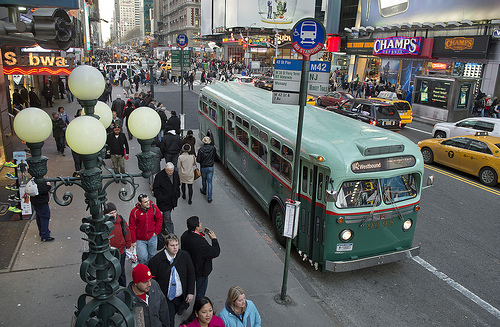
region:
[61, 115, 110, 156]
A big white lamp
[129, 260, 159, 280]
A red stylish cap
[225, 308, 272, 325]
A sky blue jacket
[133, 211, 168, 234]
A beautiful red jacket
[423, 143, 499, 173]
A yellow taxi vehicle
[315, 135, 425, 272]
A big green bus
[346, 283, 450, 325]
A grey tarmacked road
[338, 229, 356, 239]
A small head light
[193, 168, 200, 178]
A small brown bag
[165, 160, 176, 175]
A white haired head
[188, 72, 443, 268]
green bus parked on street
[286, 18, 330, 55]
blue, white, and red bus stop sign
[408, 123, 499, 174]
yellow cab on street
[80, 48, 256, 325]
people walking down sidewalk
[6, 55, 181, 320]
street light with four bulbs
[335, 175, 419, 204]
front window of green bus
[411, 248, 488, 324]
white line on road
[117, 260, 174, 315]
man wearing red hat with white logo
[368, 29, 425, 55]
champs sign across street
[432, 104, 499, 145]
white car driving down street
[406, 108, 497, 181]
the car is yellow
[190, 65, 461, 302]
the bus is green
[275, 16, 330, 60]
the sign is blue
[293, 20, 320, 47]
white bus on sign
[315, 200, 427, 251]
lights on bus are on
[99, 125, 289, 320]
people standing on sidewalk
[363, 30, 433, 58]
white letters on the sign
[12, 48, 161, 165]
street lights are white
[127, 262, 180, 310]
man is wearing a hat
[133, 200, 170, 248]
man's jacket is red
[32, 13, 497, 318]
A busy city street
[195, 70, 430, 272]
A two tone green bus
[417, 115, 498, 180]
A yellow taxi cab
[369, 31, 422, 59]
A sign that says Champs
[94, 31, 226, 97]
People and cars on the street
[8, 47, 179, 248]
A gree light pole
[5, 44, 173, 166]
Five globes on a light pole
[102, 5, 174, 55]
Sky scrapers in the distance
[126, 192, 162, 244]
A man wearing a red jacket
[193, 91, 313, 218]
A red strip on a bus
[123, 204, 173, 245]
the jacket is black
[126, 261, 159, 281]
the hat is red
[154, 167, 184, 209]
the jacket is black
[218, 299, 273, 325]
the jacket is blue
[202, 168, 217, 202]
the jeans are blue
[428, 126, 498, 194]
the taxi is yellow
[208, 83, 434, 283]
the bus is blue and green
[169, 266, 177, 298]
the tie is blue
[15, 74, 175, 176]
the light bulbs are five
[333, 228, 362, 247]
the lights are round